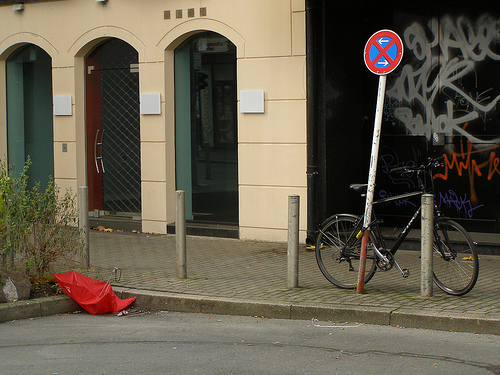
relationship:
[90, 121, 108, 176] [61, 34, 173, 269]
handle on door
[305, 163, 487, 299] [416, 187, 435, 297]
bicycle beside post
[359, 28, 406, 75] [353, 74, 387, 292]
red sign on pole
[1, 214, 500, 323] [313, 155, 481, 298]
sidewalk near bicycle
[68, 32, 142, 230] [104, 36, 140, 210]
door has mesh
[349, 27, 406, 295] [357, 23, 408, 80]
pole has sign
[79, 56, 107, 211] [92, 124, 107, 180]
red door has silver handle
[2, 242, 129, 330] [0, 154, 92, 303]
garbage near bushes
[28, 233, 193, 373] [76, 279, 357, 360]
umbrella on ground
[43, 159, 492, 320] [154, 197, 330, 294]
sidewalk has poles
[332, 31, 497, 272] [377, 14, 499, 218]
building has graffiti